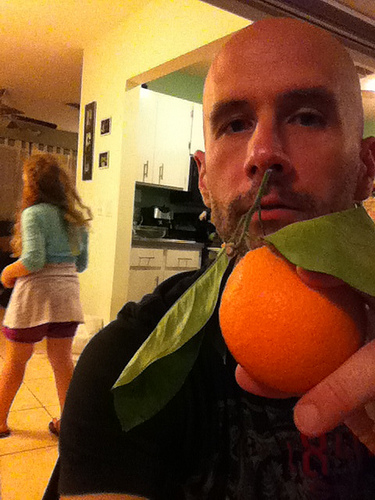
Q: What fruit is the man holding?
A: Orange.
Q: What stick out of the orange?
A: Stem.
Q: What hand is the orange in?
A: Left.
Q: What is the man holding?
A: An orange.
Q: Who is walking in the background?
A: A woman.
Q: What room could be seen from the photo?
A: Kitchen.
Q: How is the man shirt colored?
A: Black.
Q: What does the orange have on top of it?
A: Leaves.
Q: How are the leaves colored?
A: Green.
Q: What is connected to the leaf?
A: A stem.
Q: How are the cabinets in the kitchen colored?
A: White.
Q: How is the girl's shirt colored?
A: Blue.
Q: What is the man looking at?
A: The camera.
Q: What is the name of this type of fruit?
A: Orange.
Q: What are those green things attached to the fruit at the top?
A: Leaves.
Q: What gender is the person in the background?
A: Female.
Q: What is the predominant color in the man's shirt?
A: Black.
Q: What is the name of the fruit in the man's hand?
A: Orange.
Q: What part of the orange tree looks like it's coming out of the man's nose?
A: Leaf.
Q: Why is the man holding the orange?
A: The man is about to eat it.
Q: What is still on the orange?
A: A stem with leaves.